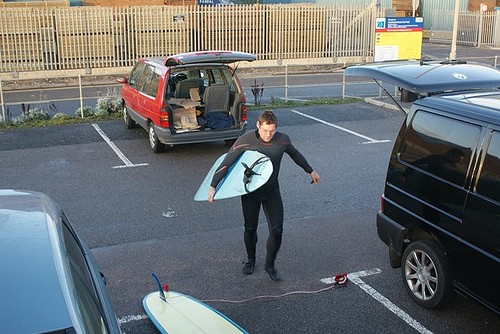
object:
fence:
[2, 5, 395, 71]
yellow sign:
[374, 25, 424, 63]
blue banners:
[373, 13, 428, 26]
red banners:
[368, 25, 423, 30]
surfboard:
[192, 149, 274, 202]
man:
[206, 110, 321, 281]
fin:
[148, 272, 165, 302]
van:
[118, 51, 255, 148]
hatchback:
[162, 47, 254, 137]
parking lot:
[0, 72, 499, 332]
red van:
[117, 50, 256, 150]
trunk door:
[162, 47, 256, 141]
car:
[131, 46, 243, 140]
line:
[85, 117, 150, 172]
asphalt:
[113, 128, 377, 303]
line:
[344, 277, 409, 332]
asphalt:
[325, 263, 411, 334]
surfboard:
[136, 272, 253, 331]